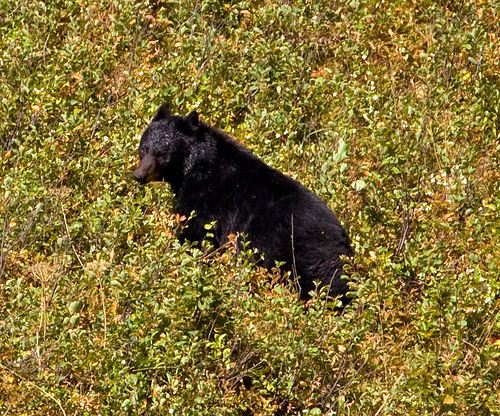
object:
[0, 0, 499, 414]
daytime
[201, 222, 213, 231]
leaf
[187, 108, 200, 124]
ear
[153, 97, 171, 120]
ear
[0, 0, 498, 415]
trees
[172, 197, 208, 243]
legs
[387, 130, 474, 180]
ground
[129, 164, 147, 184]
black nose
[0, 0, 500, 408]
shrubs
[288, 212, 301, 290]
twig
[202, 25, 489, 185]
stems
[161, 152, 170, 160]
left eye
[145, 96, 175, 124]
shirt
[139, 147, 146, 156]
eye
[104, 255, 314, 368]
grass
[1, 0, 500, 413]
field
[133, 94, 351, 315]
bear